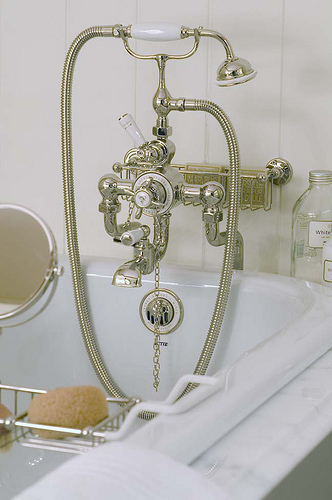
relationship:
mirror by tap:
[1, 205, 59, 327] [116, 221, 155, 251]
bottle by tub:
[287, 168, 331, 280] [0, 244, 331, 498]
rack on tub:
[0, 371, 225, 450] [0, 244, 331, 498]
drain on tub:
[142, 285, 182, 334] [0, 244, 331, 498]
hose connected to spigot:
[63, 25, 242, 423] [117, 17, 257, 91]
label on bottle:
[307, 219, 330, 275] [287, 168, 331, 280]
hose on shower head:
[63, 25, 242, 423] [213, 53, 258, 89]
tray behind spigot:
[157, 153, 298, 210] [117, 17, 257, 91]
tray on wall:
[157, 153, 298, 210] [0, 1, 330, 277]